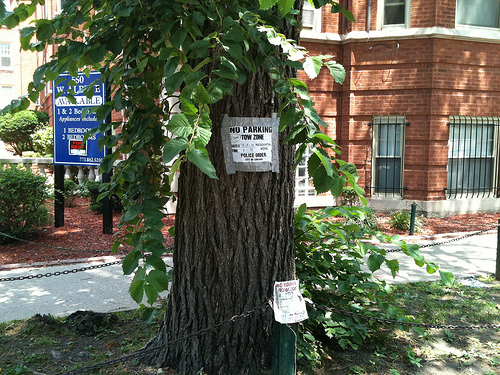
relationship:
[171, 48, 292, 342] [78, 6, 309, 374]
trunk of tree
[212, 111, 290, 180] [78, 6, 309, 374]
sign on tree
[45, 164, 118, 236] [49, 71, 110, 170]
stick holds sign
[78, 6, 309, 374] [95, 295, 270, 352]
tree has chain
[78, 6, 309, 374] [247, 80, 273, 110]
tree has bark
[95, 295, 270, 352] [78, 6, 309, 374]
chain along tree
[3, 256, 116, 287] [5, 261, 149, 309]
chain along sidewalk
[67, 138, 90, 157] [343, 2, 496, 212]
sign on building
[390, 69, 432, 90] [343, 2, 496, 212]
red brick building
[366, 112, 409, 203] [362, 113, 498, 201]
bars on window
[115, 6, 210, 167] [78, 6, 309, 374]
foliage on tree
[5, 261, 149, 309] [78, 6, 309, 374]
sidewalk behind tree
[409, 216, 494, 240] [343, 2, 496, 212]
gravel by build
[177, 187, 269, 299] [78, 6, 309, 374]
grooves in tree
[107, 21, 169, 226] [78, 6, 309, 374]
leaves on tree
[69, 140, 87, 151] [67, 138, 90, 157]
words on sign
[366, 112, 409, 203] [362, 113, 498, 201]
bars on windows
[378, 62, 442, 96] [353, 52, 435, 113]
bricks on wall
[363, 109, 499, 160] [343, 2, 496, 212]
windows in build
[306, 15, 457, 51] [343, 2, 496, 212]
lines in build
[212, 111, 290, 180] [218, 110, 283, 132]
sign has tape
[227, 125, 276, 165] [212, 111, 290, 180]
no parking sign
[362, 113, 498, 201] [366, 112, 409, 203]
window with bars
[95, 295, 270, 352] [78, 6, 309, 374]
chain on tree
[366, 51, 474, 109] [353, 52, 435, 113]
shade on wall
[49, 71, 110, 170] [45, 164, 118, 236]
sign on post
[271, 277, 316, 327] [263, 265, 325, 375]
poster hanging low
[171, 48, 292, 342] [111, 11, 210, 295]
trunk has branches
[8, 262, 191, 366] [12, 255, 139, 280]
fence of chains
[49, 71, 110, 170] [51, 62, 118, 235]
sign about housing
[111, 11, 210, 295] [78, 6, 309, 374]
branches on tree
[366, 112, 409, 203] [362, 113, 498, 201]
bars covering window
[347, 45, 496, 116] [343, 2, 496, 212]
rows of build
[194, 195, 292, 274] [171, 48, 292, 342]
texture of trunk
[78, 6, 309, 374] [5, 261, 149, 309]
tree by sidewalk